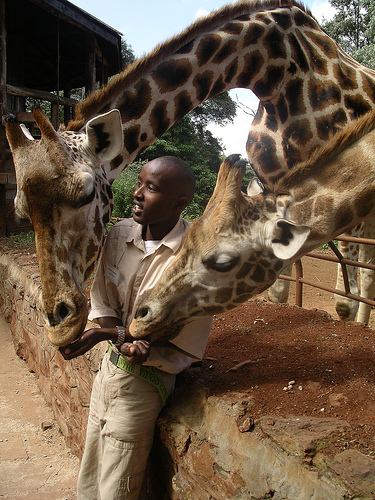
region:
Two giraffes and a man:
[0, 0, 372, 498]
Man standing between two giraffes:
[59, 146, 213, 497]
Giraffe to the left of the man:
[126, 113, 366, 330]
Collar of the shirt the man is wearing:
[124, 213, 189, 253]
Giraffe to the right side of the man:
[2, 0, 370, 348]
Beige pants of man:
[73, 414, 155, 494]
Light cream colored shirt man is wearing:
[102, 213, 207, 376]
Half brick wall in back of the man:
[0, 254, 357, 497]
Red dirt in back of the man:
[202, 294, 372, 454]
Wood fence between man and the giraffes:
[289, 224, 373, 332]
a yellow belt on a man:
[103, 346, 172, 401]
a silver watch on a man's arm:
[113, 320, 128, 349]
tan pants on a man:
[73, 346, 171, 498]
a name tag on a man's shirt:
[100, 262, 121, 284]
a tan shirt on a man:
[88, 217, 217, 371]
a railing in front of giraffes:
[264, 229, 372, 325]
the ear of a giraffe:
[263, 217, 313, 262]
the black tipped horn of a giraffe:
[223, 155, 252, 221]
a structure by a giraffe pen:
[0, 1, 130, 168]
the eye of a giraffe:
[207, 249, 242, 273]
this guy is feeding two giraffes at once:
[40, 150, 218, 378]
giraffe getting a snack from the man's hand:
[1, 103, 128, 363]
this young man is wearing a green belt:
[102, 339, 172, 404]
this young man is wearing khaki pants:
[74, 341, 171, 498]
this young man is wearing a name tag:
[101, 257, 124, 285]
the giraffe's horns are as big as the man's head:
[130, 150, 252, 230]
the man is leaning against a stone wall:
[77, 317, 276, 498]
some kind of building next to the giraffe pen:
[2, 1, 126, 145]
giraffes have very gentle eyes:
[198, 242, 246, 275]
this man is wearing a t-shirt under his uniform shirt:
[139, 234, 163, 255]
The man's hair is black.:
[132, 153, 198, 226]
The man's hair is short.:
[127, 158, 194, 224]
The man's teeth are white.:
[133, 202, 142, 214]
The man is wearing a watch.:
[111, 324, 124, 342]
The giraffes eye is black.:
[207, 254, 240, 273]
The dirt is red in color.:
[238, 321, 341, 375]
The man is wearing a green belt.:
[95, 344, 176, 407]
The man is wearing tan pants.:
[68, 347, 173, 498]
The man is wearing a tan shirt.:
[89, 155, 207, 373]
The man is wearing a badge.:
[102, 259, 121, 286]